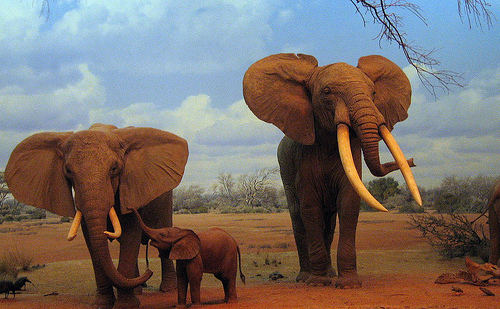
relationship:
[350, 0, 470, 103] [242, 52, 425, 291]
branch over elephant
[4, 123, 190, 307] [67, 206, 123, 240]
elephant has tusk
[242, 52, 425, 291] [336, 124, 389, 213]
elephant has tusk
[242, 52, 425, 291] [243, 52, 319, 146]
elephant has ear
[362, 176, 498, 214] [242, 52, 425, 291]
trees behind elephant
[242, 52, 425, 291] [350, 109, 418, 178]
elephant has trunk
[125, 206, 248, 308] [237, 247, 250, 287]
elephant has tail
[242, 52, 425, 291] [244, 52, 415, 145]
elephant has head